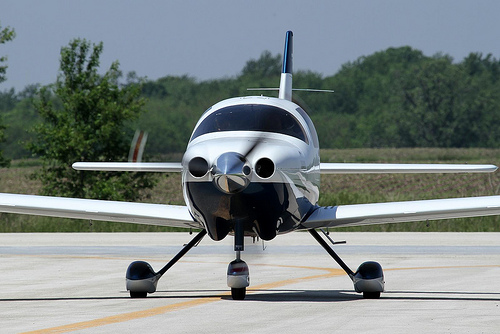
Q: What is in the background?
A: Trees.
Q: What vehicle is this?
A: Airplane.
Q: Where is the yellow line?
A: ON THE GROUND.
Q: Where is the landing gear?
A: Beneath the plane.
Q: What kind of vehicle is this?
A: Airplane.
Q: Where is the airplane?
A: Tarmac.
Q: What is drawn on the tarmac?
A: Yellow line.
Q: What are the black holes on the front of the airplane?
A: Headlights.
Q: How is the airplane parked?
A: On wheels.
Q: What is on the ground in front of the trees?
A: Grass field.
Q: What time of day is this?
A: Daylight hours.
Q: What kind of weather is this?
A: Clear and sunny.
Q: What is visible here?
A: Plane.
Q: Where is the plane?
A: On the runway.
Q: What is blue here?
A: The sky.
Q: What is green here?
A: The trees.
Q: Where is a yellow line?
A: On the runway.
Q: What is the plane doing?
A: Waiting.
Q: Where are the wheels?
A: Under the plane.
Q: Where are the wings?
A: On the plane.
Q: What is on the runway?
A: Airplane.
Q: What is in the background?
A: Trees.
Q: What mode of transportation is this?
A: An airplane.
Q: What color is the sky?
A: Purpleish blue.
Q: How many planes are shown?
A: 1.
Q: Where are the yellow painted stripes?
A: On the runway.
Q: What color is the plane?
A: White.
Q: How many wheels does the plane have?
A: 3.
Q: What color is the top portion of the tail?
A: Black.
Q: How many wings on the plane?
A: 2.